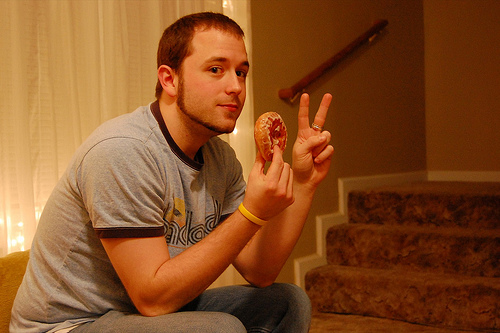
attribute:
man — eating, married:
[9, 12, 321, 331]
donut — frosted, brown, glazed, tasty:
[254, 107, 288, 161]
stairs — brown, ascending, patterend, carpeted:
[295, 165, 498, 332]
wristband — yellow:
[82, 146, 297, 316]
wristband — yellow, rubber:
[233, 202, 272, 230]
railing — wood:
[276, 16, 394, 107]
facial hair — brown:
[173, 68, 238, 136]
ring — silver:
[312, 121, 325, 133]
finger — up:
[311, 88, 334, 135]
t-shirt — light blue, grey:
[9, 102, 255, 332]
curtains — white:
[0, 0, 222, 254]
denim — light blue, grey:
[67, 280, 317, 332]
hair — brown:
[154, 11, 246, 99]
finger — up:
[296, 92, 313, 130]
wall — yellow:
[252, 1, 500, 280]